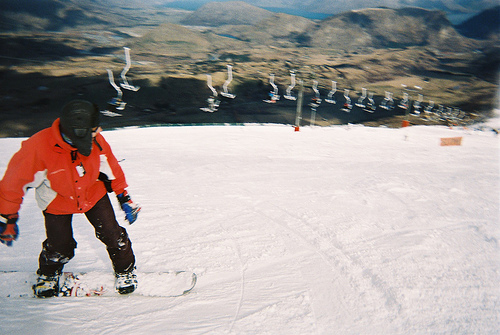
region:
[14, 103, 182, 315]
a guy riding a snowboard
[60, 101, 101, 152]
the hat of a guy snowboarding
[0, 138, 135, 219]
the coat of a guy snowboarding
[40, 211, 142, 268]
the pants of a guy snowboarding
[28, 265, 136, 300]
the boots of a guy snowboarding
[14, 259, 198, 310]
the snowboard of a guy snowboarding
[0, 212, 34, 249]
the gloves of a guy snowboarding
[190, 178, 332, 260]
a patch of freshly fallen snow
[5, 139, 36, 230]
the arm of a guy snowboarding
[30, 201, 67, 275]
the leg of a guy snowboarding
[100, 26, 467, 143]
ski lift behind the snow boarder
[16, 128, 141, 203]
person wearing an orange jacket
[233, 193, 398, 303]
snow covering the ground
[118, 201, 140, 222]
person is wearing gloves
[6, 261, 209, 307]
person is own a snowboard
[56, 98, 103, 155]
person is wearing a hat with flaps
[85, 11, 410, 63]
mountains are in the distance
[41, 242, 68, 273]
snow is on the person's pants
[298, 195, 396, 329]
tracks in the snow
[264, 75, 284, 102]
person on the ski lift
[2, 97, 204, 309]
A person on a snowboard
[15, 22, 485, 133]
A ski lift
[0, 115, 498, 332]
Snow covering the ground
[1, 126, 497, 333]
White snow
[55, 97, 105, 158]
A black helmet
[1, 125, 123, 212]
A red and white winter coat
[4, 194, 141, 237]
Winter gloves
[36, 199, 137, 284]
A pair of black winter pants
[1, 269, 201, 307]
A snowboard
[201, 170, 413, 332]
Marks in the snow from skiers and snowboarders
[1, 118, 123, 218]
an orange and white parka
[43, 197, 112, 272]
pair of brown snow pants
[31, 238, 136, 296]
snow covered snow boots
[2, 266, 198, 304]
a snow board being used in the snow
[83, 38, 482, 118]
a chair lift to the top of the slope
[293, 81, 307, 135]
pole holds the lift line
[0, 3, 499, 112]
mountains in the distance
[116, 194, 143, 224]
a glove with a blue palm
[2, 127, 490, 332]
many prints in the snow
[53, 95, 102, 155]
a black head covering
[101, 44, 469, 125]
Chairs on the ski lift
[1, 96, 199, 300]
A snowboarder wearing a black hat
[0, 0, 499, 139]
Mountains in the background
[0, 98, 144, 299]
A person wearing a red jacket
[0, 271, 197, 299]
A snowboard with snow on it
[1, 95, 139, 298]
A person wearing gloves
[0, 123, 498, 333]
Snow on the ground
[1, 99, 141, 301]
A person wearing black pants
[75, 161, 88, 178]
A ski lift pass